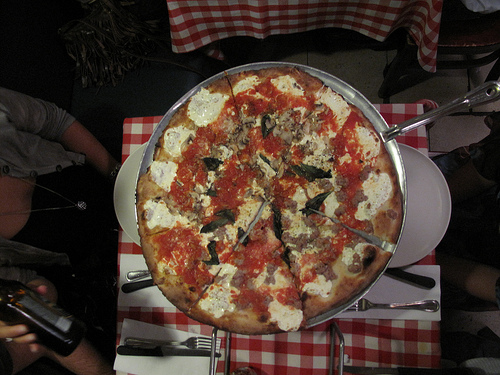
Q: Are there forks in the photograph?
A: Yes, there is a fork.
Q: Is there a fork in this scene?
A: Yes, there is a fork.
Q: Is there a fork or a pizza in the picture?
A: Yes, there is a fork.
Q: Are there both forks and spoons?
A: No, there is a fork but no spoons.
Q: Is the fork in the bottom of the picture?
A: Yes, the fork is in the bottom of the image.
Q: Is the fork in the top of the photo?
A: No, the fork is in the bottom of the image.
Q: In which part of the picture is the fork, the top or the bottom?
A: The fork is in the bottom of the image.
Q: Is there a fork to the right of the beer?
A: Yes, there is a fork to the right of the beer.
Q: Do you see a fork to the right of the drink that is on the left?
A: Yes, there is a fork to the right of the beer.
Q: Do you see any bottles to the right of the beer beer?
A: No, there is a fork to the right of the beer.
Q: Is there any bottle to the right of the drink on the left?
A: No, there is a fork to the right of the beer.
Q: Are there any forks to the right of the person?
A: Yes, there is a fork to the right of the person.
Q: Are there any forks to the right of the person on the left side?
A: Yes, there is a fork to the right of the person.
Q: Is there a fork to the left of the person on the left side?
A: No, the fork is to the right of the person.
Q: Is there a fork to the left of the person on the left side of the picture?
A: No, the fork is to the right of the person.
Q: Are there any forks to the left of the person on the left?
A: No, the fork is to the right of the person.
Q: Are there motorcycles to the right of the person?
A: No, there is a fork to the right of the person.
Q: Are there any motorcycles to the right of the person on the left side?
A: No, there is a fork to the right of the person.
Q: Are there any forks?
A: Yes, there is a fork.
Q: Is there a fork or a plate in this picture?
A: Yes, there is a fork.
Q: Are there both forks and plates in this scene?
A: Yes, there are both a fork and a plate.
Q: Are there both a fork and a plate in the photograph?
A: Yes, there are both a fork and a plate.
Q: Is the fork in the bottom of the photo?
A: Yes, the fork is in the bottom of the image.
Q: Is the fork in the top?
A: No, the fork is in the bottom of the image.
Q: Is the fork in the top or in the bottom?
A: The fork is in the bottom of the image.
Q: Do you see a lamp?
A: No, there are no lamps.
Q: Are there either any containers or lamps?
A: No, there are no lamps or containers.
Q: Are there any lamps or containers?
A: No, there are no lamps or containers.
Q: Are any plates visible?
A: Yes, there is a plate.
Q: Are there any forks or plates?
A: Yes, there is a plate.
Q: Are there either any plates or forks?
A: Yes, there is a plate.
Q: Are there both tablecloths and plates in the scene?
A: Yes, there are both a plate and a tablecloth.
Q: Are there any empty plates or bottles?
A: Yes, there is an empty plate.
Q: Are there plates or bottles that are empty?
A: Yes, the plate is empty.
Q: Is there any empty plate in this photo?
A: Yes, there is an empty plate.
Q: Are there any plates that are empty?
A: Yes, there is a plate that is empty.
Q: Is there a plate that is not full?
A: Yes, there is a empty plate.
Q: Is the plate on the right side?
A: Yes, the plate is on the right of the image.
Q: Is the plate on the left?
A: No, the plate is on the right of the image.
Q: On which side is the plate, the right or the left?
A: The plate is on the right of the image.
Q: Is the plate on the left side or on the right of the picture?
A: The plate is on the right of the image.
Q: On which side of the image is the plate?
A: The plate is on the right of the image.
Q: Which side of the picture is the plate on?
A: The plate is on the right of the image.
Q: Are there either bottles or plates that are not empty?
A: No, there is a plate but it is empty.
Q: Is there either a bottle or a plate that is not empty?
A: No, there is a plate but it is empty.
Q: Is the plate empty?
A: Yes, the plate is empty.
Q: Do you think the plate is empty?
A: Yes, the plate is empty.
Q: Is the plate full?
A: No, the plate is empty.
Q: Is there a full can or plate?
A: No, there is a plate but it is empty.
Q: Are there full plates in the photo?
A: No, there is a plate but it is empty.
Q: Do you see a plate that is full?
A: No, there is a plate but it is empty.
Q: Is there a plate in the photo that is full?
A: No, there is a plate but it is empty.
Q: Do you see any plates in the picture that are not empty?
A: No, there is a plate but it is empty.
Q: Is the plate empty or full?
A: The plate is empty.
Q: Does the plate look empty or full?
A: The plate is empty.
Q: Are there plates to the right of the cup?
A: Yes, there is a plate to the right of the cup.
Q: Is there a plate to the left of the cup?
A: No, the plate is to the right of the cup.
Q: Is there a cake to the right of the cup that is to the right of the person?
A: No, there is a plate to the right of the cup.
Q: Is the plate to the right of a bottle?
A: No, the plate is to the right of a cup.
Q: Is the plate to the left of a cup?
A: No, the plate is to the right of a cup.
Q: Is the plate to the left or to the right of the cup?
A: The plate is to the right of the cup.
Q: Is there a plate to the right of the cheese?
A: Yes, there is a plate to the right of the cheese.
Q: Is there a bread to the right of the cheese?
A: No, there is a plate to the right of the cheese.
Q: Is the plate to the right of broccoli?
A: No, the plate is to the right of the cheese.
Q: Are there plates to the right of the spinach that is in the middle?
A: Yes, there is a plate to the right of the spinach.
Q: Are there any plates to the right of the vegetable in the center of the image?
A: Yes, there is a plate to the right of the spinach.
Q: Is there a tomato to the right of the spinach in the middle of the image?
A: No, there is a plate to the right of the spinach.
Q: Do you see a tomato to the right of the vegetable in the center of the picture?
A: No, there is a plate to the right of the spinach.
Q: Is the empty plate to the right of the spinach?
A: Yes, the plate is to the right of the spinach.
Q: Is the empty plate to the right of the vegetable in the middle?
A: Yes, the plate is to the right of the spinach.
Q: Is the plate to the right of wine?
A: No, the plate is to the right of the spinach.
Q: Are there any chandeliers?
A: No, there are no chandeliers.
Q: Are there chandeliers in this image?
A: No, there are no chandeliers.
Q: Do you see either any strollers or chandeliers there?
A: No, there are no chandeliers or strollers.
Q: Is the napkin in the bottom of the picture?
A: Yes, the napkin is in the bottom of the image.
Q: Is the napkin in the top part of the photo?
A: No, the napkin is in the bottom of the image.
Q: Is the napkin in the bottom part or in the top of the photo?
A: The napkin is in the bottom of the image.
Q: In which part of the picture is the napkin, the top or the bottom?
A: The napkin is in the bottom of the image.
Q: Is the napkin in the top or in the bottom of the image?
A: The napkin is in the bottom of the image.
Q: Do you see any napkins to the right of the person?
A: Yes, there is a napkin to the right of the person.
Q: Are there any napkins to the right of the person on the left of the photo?
A: Yes, there is a napkin to the right of the person.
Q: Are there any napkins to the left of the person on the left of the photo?
A: No, the napkin is to the right of the person.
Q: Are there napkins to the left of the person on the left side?
A: No, the napkin is to the right of the person.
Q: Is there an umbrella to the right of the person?
A: No, there is a napkin to the right of the person.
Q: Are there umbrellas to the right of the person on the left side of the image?
A: No, there is a napkin to the right of the person.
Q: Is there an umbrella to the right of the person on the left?
A: No, there is a napkin to the right of the person.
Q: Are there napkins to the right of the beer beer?
A: Yes, there is a napkin to the right of the beer.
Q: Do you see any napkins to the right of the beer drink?
A: Yes, there is a napkin to the right of the beer.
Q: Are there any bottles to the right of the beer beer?
A: No, there is a napkin to the right of the beer.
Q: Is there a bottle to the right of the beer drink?
A: No, there is a napkin to the right of the beer.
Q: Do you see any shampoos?
A: No, there are no shampoos.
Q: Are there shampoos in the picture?
A: No, there are no shampoos.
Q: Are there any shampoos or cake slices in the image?
A: No, there are no shampoos or cake slices.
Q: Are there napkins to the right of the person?
A: Yes, there is a napkin to the right of the person.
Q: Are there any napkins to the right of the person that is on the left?
A: Yes, there is a napkin to the right of the person.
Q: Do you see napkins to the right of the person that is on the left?
A: Yes, there is a napkin to the right of the person.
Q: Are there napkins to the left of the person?
A: No, the napkin is to the right of the person.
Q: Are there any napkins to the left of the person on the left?
A: No, the napkin is to the right of the person.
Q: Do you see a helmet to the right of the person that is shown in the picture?
A: No, there is a napkin to the right of the person.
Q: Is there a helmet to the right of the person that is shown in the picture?
A: No, there is a napkin to the right of the person.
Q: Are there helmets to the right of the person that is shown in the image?
A: No, there is a napkin to the right of the person.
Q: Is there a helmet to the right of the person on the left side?
A: No, there is a napkin to the right of the person.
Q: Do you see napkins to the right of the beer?
A: Yes, there is a napkin to the right of the beer.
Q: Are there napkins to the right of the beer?
A: Yes, there is a napkin to the right of the beer.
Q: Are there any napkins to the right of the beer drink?
A: Yes, there is a napkin to the right of the beer.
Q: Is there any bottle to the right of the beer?
A: No, there is a napkin to the right of the beer.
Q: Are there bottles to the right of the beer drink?
A: No, there is a napkin to the right of the beer.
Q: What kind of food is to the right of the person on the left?
A: The food is a mushroom.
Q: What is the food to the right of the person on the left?
A: The food is a mushroom.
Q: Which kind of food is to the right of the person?
A: The food is a mushroom.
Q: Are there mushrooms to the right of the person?
A: Yes, there is a mushroom to the right of the person.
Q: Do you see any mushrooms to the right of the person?
A: Yes, there is a mushroom to the right of the person.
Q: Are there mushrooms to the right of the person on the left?
A: Yes, there is a mushroom to the right of the person.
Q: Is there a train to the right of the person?
A: No, there is a mushroom to the right of the person.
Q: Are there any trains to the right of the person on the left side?
A: No, there is a mushroom to the right of the person.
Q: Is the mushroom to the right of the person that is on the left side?
A: Yes, the mushroom is to the right of the person.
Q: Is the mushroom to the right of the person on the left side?
A: Yes, the mushroom is to the right of the person.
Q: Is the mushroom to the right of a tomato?
A: No, the mushroom is to the right of the person.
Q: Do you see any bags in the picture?
A: No, there are no bags.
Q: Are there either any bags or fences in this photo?
A: No, there are no bags or fences.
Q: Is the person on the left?
A: Yes, the person is on the left of the image.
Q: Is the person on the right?
A: No, the person is on the left of the image.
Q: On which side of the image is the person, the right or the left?
A: The person is on the left of the image.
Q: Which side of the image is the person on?
A: The person is on the left of the image.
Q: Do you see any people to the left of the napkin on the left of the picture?
A: Yes, there is a person to the left of the napkin.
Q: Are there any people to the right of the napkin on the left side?
A: No, the person is to the left of the napkin.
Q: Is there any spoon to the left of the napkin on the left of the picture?
A: No, there is a person to the left of the napkin.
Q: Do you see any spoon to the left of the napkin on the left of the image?
A: No, there is a person to the left of the napkin.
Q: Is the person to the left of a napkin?
A: Yes, the person is to the left of a napkin.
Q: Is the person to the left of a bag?
A: No, the person is to the left of a napkin.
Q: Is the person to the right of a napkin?
A: No, the person is to the left of a napkin.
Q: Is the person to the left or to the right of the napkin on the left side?
A: The person is to the left of the napkin.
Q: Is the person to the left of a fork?
A: Yes, the person is to the left of a fork.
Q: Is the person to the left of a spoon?
A: No, the person is to the left of a fork.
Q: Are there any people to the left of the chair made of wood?
A: Yes, there is a person to the left of the chair.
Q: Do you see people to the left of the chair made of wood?
A: Yes, there is a person to the left of the chair.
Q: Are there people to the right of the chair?
A: No, the person is to the left of the chair.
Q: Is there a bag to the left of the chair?
A: No, there is a person to the left of the chair.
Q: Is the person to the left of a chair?
A: Yes, the person is to the left of a chair.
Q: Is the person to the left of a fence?
A: No, the person is to the left of a chair.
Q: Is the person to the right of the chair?
A: No, the person is to the left of the chair.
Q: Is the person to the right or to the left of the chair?
A: The person is to the left of the chair.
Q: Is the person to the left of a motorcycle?
A: No, the person is to the left of the napkin.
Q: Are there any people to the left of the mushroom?
A: Yes, there is a person to the left of the mushroom.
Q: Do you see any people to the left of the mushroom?
A: Yes, there is a person to the left of the mushroom.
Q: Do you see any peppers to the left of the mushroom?
A: No, there is a person to the left of the mushroom.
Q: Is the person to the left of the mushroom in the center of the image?
A: Yes, the person is to the left of the mushroom.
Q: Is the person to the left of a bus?
A: No, the person is to the left of the mushroom.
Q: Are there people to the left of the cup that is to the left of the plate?
A: Yes, there is a person to the left of the cup.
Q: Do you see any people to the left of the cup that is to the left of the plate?
A: Yes, there is a person to the left of the cup.